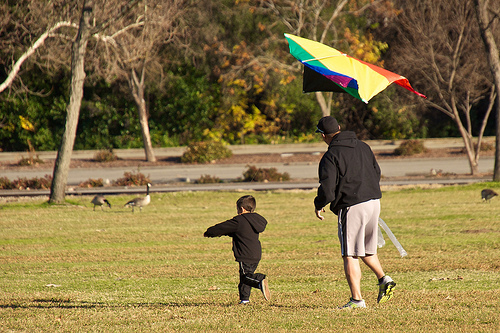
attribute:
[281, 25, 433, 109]
kite — multi colored, airborne, colorful, multicolored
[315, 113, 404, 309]
man — walking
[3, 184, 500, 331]
grass — greenish brown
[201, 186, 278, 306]
little boy — running, small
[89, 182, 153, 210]
geese — large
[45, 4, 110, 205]
tree trunk — brown, bare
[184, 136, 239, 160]
bush — small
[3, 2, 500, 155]
trees — green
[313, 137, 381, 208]
hoodie — black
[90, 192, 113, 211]
goose — grazing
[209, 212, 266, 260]
sweatshirt — black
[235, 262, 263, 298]
pants — black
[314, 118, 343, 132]
hat — black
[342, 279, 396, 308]
sneakers — black, yellow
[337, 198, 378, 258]
shorts — gray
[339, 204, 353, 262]
line — black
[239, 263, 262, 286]
line — white